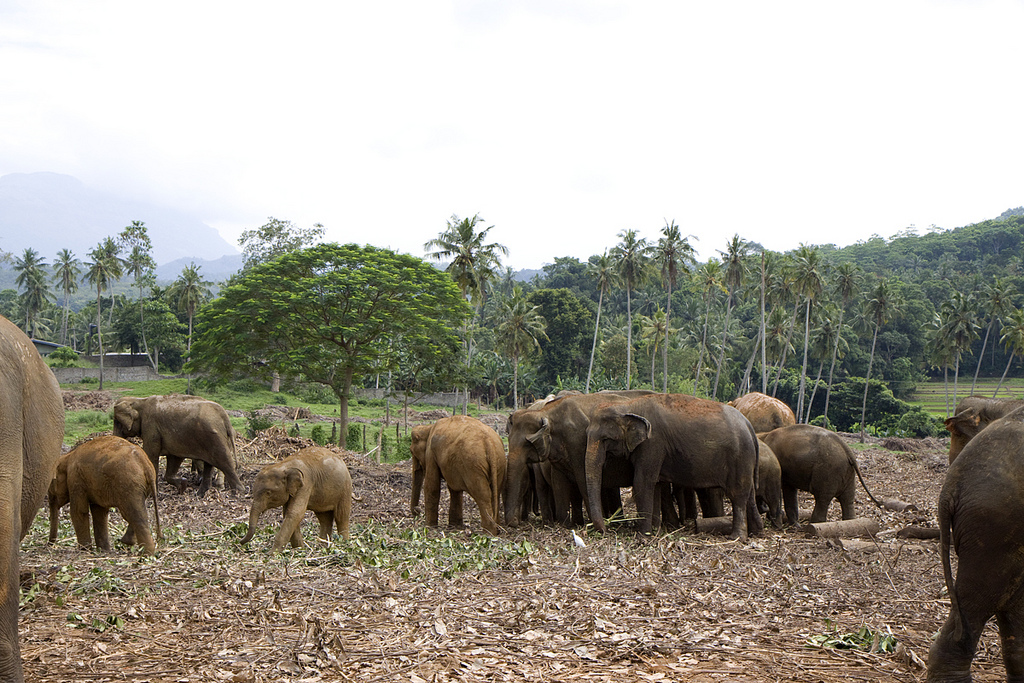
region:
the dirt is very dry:
[481, 520, 810, 673]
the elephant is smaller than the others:
[201, 413, 389, 551]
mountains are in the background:
[1, 138, 249, 297]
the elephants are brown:
[481, 359, 789, 533]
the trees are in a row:
[547, 203, 912, 426]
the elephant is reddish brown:
[368, 373, 518, 538]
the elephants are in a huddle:
[394, 332, 894, 577]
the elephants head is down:
[30, 409, 180, 561]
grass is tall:
[424, 523, 507, 565]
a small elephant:
[241, 446, 363, 538]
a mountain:
[25, 178, 103, 221]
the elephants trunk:
[581, 440, 611, 535]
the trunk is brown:
[576, 431, 631, 524]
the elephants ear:
[625, 413, 655, 442]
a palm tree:
[446, 212, 498, 276]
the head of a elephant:
[217, 445, 313, 544]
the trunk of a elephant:
[555, 438, 620, 528]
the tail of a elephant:
[467, 434, 515, 511]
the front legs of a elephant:
[252, 476, 319, 553]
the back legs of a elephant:
[445, 445, 515, 545]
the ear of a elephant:
[256, 419, 327, 502]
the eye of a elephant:
[571, 394, 628, 462]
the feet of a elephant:
[87, 515, 195, 563]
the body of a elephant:
[94, 366, 306, 466]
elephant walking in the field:
[217, 439, 363, 554]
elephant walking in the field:
[53, 429, 177, 566]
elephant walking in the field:
[104, 382, 248, 494]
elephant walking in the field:
[389, 404, 513, 523]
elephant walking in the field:
[578, 391, 762, 532]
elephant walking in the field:
[885, 402, 1022, 679]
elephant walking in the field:
[755, 413, 863, 516]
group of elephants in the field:
[407, 350, 891, 550]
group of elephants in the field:
[37, 366, 385, 581]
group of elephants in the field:
[922, 397, 1018, 647]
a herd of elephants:
[15, 338, 1022, 632]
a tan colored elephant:
[397, 383, 516, 548]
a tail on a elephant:
[909, 418, 993, 646]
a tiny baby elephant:
[215, 432, 389, 576]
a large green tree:
[182, 222, 492, 447]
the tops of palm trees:
[419, 211, 931, 338]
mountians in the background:
[0, 167, 563, 297]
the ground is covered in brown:
[376, 585, 769, 662]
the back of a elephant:
[117, 446, 185, 583]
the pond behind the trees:
[51, 356, 178, 388]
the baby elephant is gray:
[241, 439, 353, 554]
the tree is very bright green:
[180, 242, 469, 448]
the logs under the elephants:
[813, 514, 943, 556]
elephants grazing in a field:
[1, 317, 1013, 678]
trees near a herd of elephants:
[2, 210, 1018, 416]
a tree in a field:
[184, 229, 482, 449]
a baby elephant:
[242, 438, 360, 560]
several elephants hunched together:
[403, 379, 887, 553]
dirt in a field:
[18, 537, 932, 678]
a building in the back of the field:
[26, 327, 162, 398]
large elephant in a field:
[579, 387, 764, 537]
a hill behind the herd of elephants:
[492, 201, 1020, 392]